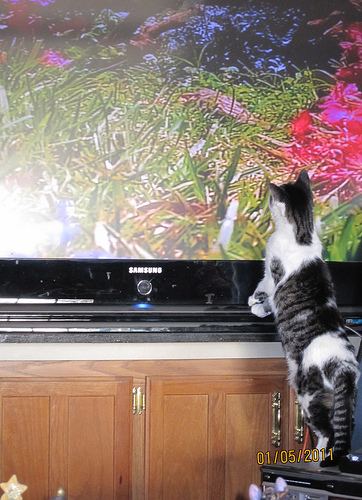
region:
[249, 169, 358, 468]
a cat watching TV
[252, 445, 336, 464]
date 01/05/2011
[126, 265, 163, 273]
the samsung white logo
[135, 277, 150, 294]
the on/off TV button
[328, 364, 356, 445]
the cat's tail with different gray scale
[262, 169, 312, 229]
the cat's head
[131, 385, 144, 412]
a golden hinge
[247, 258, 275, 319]
the white and gray cat's forelegs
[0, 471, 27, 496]
a yellow star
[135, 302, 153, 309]
An on Blue indicator light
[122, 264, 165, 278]
samsung printed in white on bottom of television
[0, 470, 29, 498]
yellow star on cabinet door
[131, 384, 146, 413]
gold hinge on door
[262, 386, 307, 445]
gold handles of cabinet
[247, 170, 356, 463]
gray and white cat standing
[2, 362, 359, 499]
cabinet with two doors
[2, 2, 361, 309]
black framed flatscreen tv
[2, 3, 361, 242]
screen of tv showing flowers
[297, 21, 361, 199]
pink flowers on tv screen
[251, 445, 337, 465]
timestamp in yellow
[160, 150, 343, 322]
cat looking at the TV screen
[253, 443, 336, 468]
date on camera 01/05/2011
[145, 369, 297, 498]
wooden doors on cabinet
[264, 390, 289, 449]
golden handles on wooden doors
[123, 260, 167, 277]
Samsung logo on TV monitor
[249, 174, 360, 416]
black and white cat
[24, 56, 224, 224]
large grass on TV screen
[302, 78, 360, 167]
red flowers on TV screen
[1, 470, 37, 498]
star shape next to wood cabinet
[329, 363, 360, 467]
cat's black striped tail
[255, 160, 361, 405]
Cat watching the tv.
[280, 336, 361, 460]
Tail of the cat.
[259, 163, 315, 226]
Head of the cat.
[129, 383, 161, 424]
Hinge on the door.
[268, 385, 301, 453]
Handle on the cabinet.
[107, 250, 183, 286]
Brand of the TV.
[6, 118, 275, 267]
Screen on the TV.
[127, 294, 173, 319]
Light on the TV.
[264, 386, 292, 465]
Brass knob on the cabinet.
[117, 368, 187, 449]
Metal hinges on the cabinet.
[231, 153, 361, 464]
cat watching the television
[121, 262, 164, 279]
samsung written in white on tv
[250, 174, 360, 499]
cat standing on electronics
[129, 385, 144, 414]
hinge of cabinet door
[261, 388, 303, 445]
handles of cabinet door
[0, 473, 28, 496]
star on wooden door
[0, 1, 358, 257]
tv screen showing flowers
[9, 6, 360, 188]
pink flowers on tv screen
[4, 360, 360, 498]
cabinet television is on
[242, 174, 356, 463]
gray and white cat